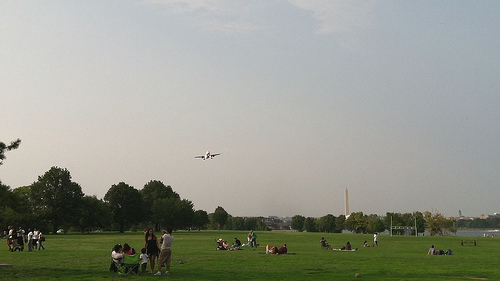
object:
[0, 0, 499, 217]
blue sky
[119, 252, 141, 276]
chair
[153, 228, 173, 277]
people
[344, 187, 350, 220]
monument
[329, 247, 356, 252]
blanket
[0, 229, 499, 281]
ground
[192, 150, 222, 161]
airplane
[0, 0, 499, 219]
cloud